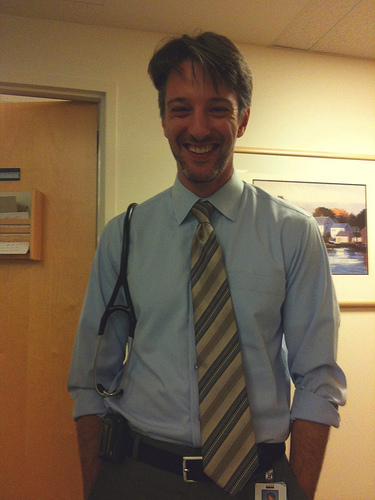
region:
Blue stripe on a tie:
[185, 237, 210, 284]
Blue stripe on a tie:
[196, 316, 206, 339]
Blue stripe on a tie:
[193, 352, 246, 397]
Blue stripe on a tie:
[190, 427, 226, 458]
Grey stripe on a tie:
[209, 456, 229, 491]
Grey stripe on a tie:
[196, 403, 217, 426]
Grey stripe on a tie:
[197, 341, 213, 365]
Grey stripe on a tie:
[187, 236, 201, 254]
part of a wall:
[347, 421, 353, 430]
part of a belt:
[139, 455, 146, 464]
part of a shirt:
[174, 432, 177, 438]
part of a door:
[59, 391, 68, 407]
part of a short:
[191, 476, 200, 497]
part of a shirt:
[322, 385, 329, 411]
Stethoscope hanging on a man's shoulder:
[94, 196, 139, 397]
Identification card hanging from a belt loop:
[252, 461, 286, 499]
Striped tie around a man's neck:
[186, 197, 261, 498]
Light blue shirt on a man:
[65, 174, 345, 447]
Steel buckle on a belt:
[180, 453, 202, 484]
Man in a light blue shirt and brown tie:
[67, 30, 347, 498]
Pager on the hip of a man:
[98, 410, 130, 463]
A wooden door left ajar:
[1, 97, 101, 497]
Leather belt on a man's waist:
[128, 438, 229, 481]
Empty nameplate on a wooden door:
[0, 168, 22, 182]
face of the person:
[144, 44, 257, 164]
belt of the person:
[169, 446, 231, 490]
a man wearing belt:
[98, 419, 281, 483]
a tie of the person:
[163, 241, 293, 484]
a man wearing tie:
[171, 254, 284, 492]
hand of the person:
[47, 333, 111, 462]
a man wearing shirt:
[75, 219, 331, 421]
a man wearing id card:
[249, 465, 280, 493]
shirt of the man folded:
[295, 393, 339, 441]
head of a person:
[135, 25, 272, 180]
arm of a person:
[32, 303, 153, 454]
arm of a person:
[271, 300, 347, 468]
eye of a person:
[167, 95, 201, 127]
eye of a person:
[207, 96, 230, 126]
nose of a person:
[179, 125, 218, 145]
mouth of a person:
[167, 135, 230, 166]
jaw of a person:
[175, 159, 225, 185]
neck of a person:
[160, 167, 239, 200]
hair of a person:
[216, 40, 248, 63]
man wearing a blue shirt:
[133, 38, 308, 346]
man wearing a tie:
[182, 188, 221, 346]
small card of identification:
[261, 476, 278, 499]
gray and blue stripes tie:
[192, 234, 263, 489]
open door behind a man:
[8, 90, 89, 201]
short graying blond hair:
[156, 50, 237, 168]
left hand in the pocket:
[270, 438, 323, 492]